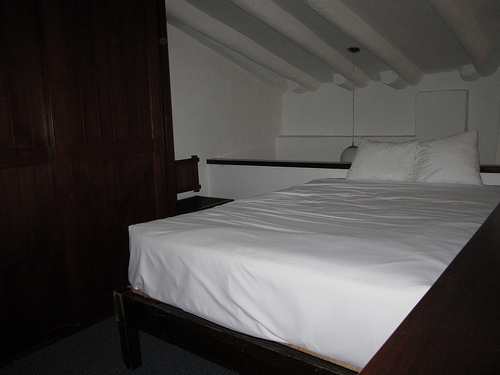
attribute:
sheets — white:
[127, 179, 498, 369]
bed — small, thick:
[116, 126, 499, 370]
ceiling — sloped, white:
[164, 2, 498, 85]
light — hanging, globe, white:
[168, 0, 327, 99]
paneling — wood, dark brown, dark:
[5, 3, 165, 373]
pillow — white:
[415, 138, 482, 186]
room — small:
[3, 4, 494, 374]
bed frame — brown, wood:
[114, 291, 330, 367]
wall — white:
[269, 84, 499, 171]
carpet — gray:
[5, 297, 234, 372]